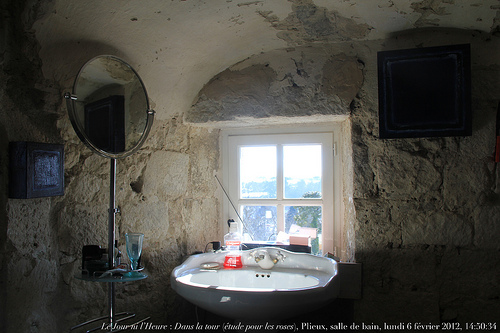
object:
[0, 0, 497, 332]
wall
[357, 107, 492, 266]
wall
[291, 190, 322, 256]
tree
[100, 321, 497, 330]
words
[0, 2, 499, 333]
photo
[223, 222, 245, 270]
bottle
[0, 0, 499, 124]
ceiling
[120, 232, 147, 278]
glass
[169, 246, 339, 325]
basin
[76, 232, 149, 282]
shelf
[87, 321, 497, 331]
photo tag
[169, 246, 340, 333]
sink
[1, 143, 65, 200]
cabinet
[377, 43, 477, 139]
box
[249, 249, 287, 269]
faucet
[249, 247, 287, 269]
handles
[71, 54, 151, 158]
mirror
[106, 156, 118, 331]
pole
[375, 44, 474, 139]
speaker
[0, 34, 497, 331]
wall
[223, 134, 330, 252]
window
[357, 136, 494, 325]
wall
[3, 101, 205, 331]
wall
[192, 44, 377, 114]
wall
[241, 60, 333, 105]
wall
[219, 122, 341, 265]
window frame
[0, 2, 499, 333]
bathroom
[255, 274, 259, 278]
hole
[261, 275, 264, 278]
hole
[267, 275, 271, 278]
hole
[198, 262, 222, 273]
soap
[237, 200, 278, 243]
pane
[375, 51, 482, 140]
television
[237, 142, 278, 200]
pane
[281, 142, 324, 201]
pane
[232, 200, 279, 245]
pane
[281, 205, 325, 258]
pane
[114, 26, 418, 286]
wall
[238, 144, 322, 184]
light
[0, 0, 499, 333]
picture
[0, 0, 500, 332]
room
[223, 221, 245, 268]
item